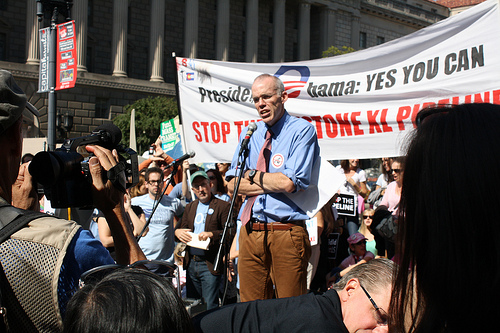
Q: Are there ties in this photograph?
A: Yes, there is a tie.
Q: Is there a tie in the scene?
A: Yes, there is a tie.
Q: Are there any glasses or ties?
A: Yes, there is a tie.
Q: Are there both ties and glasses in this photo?
A: Yes, there are both a tie and glasses.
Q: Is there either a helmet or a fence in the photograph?
A: No, there are no fences or helmets.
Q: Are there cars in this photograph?
A: No, there are no cars.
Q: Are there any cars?
A: No, there are no cars.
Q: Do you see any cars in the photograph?
A: No, there are no cars.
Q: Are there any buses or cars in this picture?
A: No, there are no cars or buses.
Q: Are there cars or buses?
A: No, there are no cars or buses.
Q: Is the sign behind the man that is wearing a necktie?
A: Yes, the sign is behind the man.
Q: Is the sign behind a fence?
A: No, the sign is behind the man.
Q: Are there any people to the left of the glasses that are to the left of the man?
A: Yes, there is a person to the left of the glasses.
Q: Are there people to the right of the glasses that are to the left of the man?
A: No, the person is to the left of the glasses.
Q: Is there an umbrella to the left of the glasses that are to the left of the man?
A: No, there is a person to the left of the glasses.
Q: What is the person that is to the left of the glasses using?
A: The person is using a camera.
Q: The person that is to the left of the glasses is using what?
A: The person is using a camera.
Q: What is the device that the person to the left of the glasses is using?
A: The device is a camera.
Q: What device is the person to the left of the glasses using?
A: The person is using a camera.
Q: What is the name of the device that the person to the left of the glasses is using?
A: The device is a camera.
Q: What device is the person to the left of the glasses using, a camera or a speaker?
A: The person is using a camera.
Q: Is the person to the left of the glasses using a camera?
A: Yes, the person is using a camera.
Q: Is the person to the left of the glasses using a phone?
A: No, the person is using a camera.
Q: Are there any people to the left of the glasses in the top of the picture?
A: Yes, there is a person to the left of the glasses.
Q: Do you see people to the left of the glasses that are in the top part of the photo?
A: Yes, there is a person to the left of the glasses.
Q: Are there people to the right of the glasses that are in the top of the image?
A: No, the person is to the left of the glasses.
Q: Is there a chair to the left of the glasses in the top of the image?
A: No, there is a person to the left of the glasses.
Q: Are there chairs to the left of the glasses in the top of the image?
A: No, there is a person to the left of the glasses.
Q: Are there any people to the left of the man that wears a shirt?
A: Yes, there is a person to the left of the man.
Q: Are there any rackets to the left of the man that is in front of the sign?
A: No, there is a person to the left of the man.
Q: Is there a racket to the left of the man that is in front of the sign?
A: No, there is a person to the left of the man.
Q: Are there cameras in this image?
A: Yes, there is a camera.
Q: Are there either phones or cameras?
A: Yes, there is a camera.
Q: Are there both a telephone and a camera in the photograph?
A: No, there is a camera but no phones.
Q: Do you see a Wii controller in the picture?
A: No, there are no Wii controllers.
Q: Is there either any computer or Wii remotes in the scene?
A: No, there are no Wii controllers or computers.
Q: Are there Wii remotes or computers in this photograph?
A: No, there are no Wii remotes or computers.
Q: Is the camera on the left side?
A: Yes, the camera is on the left of the image.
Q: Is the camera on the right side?
A: No, the camera is on the left of the image.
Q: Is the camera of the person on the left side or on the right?
A: The camera is on the left of the image.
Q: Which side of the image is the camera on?
A: The camera is on the left of the image.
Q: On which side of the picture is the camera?
A: The camera is on the left of the image.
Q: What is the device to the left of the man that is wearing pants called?
A: The device is a camera.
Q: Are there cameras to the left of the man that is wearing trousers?
A: Yes, there is a camera to the left of the man.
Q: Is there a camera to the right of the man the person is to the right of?
A: No, the camera is to the left of the man.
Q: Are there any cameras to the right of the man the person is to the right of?
A: No, the camera is to the left of the man.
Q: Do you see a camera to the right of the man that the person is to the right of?
A: No, the camera is to the left of the man.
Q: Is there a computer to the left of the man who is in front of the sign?
A: No, there is a camera to the left of the man.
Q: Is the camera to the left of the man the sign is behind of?
A: Yes, the camera is to the left of the man.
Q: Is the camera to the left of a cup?
A: No, the camera is to the left of the man.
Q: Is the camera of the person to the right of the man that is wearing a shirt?
A: No, the camera is to the left of the man.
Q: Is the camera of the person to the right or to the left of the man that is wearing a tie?
A: The camera is to the left of the man.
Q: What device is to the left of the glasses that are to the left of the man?
A: The device is a camera.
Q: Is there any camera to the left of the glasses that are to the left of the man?
A: Yes, there is a camera to the left of the glasses.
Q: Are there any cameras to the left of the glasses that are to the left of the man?
A: Yes, there is a camera to the left of the glasses.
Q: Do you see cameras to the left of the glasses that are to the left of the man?
A: Yes, there is a camera to the left of the glasses.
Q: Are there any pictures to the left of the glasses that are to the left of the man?
A: No, there is a camera to the left of the glasses.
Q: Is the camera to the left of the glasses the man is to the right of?
A: Yes, the camera is to the left of the glasses.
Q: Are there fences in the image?
A: No, there are no fences.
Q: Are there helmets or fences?
A: No, there are no fences or helmets.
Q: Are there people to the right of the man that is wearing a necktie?
A: Yes, there is a person to the right of the man.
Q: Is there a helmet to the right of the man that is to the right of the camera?
A: No, there is a person to the right of the man.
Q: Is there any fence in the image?
A: No, there are no fences.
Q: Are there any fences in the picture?
A: No, there are no fences.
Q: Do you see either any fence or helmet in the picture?
A: No, there are no fences or helmets.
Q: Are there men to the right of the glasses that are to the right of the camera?
A: Yes, there is a man to the right of the glasses.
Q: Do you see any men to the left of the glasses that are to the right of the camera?
A: No, the man is to the right of the glasses.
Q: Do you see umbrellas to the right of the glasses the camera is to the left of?
A: No, there is a man to the right of the glasses.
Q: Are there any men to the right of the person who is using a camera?
A: Yes, there is a man to the right of the person.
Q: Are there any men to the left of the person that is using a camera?
A: No, the man is to the right of the person.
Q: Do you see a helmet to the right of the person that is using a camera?
A: No, there is a man to the right of the person.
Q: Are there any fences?
A: No, there are no fences.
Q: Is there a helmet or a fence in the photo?
A: No, there are no fences or helmets.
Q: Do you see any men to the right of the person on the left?
A: Yes, there is a man to the right of the person.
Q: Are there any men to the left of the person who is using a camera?
A: No, the man is to the right of the person.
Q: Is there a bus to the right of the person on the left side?
A: No, there is a man to the right of the person.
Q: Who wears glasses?
A: The man wears glasses.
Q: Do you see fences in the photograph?
A: No, there are no fences.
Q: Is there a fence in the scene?
A: No, there are no fences.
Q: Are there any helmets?
A: No, there are no helmets.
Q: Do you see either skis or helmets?
A: No, there are no helmets or skis.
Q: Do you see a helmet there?
A: No, there are no helmets.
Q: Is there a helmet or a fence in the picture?
A: No, there are no helmets or fences.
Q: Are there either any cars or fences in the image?
A: No, there are no cars or fences.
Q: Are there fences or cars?
A: No, there are no cars or fences.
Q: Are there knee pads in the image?
A: No, there are no knee pads.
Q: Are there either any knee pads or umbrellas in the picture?
A: No, there are no knee pads or umbrellas.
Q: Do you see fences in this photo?
A: No, there are no fences.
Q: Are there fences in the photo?
A: No, there are no fences.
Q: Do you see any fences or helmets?
A: No, there are no fences or helmets.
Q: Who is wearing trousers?
A: The man is wearing trousers.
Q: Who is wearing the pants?
A: The man is wearing trousers.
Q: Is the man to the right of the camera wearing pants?
A: Yes, the man is wearing pants.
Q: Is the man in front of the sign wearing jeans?
A: No, the man is wearing pants.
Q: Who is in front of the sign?
A: The man is in front of the sign.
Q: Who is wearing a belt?
A: The man is wearing a belt.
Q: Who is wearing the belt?
A: The man is wearing a belt.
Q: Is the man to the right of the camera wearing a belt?
A: Yes, the man is wearing a belt.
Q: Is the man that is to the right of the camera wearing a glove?
A: No, the man is wearing a belt.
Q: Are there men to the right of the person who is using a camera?
A: Yes, there is a man to the right of the person.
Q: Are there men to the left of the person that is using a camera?
A: No, the man is to the right of the person.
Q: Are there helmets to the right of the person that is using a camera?
A: No, there is a man to the right of the person.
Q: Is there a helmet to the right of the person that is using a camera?
A: No, there is a man to the right of the person.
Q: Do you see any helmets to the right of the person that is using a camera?
A: No, there is a man to the right of the person.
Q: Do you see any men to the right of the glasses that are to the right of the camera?
A: Yes, there is a man to the right of the glasses.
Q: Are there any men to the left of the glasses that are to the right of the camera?
A: No, the man is to the right of the glasses.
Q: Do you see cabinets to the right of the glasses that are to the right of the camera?
A: No, there is a man to the right of the glasses.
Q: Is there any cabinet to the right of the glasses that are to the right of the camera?
A: No, there is a man to the right of the glasses.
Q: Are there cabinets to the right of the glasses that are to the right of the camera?
A: No, there is a man to the right of the glasses.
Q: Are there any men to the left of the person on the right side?
A: Yes, there is a man to the left of the person.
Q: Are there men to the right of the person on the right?
A: No, the man is to the left of the person.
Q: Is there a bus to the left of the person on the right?
A: No, there is a man to the left of the person.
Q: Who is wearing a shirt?
A: The man is wearing a shirt.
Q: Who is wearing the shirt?
A: The man is wearing a shirt.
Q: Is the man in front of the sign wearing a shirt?
A: Yes, the man is wearing a shirt.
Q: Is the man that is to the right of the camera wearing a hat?
A: No, the man is wearing a shirt.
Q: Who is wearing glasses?
A: The man is wearing glasses.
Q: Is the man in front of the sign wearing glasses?
A: Yes, the man is wearing glasses.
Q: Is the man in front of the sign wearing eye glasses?
A: No, the man is wearing glasses.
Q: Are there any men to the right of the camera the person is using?
A: Yes, there is a man to the right of the camera.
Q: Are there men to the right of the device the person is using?
A: Yes, there is a man to the right of the camera.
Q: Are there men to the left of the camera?
A: No, the man is to the right of the camera.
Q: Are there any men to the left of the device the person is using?
A: No, the man is to the right of the camera.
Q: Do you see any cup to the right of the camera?
A: No, there is a man to the right of the camera.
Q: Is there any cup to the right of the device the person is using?
A: No, there is a man to the right of the camera.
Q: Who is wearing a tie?
A: The man is wearing a tie.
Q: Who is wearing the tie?
A: The man is wearing a tie.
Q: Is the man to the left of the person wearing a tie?
A: Yes, the man is wearing a tie.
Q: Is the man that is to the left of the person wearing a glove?
A: No, the man is wearing a tie.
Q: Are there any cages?
A: No, there are no cages.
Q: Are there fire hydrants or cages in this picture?
A: No, there are no cages or fire hydrants.